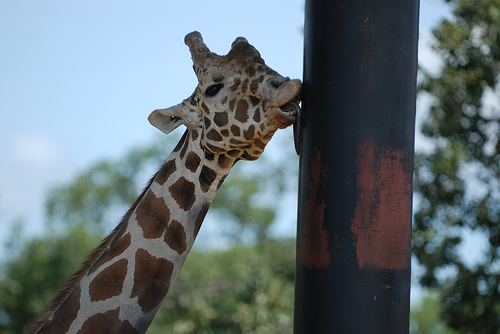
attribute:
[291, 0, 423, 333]
black pole — tall and thick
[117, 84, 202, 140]
ear — white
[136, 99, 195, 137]
ear — white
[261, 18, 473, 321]
pole — street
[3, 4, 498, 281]
sky — clear, blue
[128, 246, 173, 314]
spot — brown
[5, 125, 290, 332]
trees — distant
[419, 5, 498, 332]
tree — tall, green, leafy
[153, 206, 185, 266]
spot — brown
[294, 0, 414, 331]
post — black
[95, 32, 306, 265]
giraffe — brown and white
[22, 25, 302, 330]
giraffe — spotted, tan and brown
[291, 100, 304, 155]
tongue — black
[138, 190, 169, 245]
spot — brown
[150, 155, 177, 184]
spot — brown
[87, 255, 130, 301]
spot — brown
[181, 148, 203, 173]
spot — brown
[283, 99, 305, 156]
tongue — black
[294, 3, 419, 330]
pole — black, partially red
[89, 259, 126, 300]
spot — brown